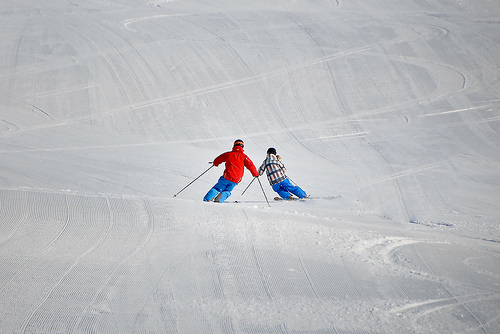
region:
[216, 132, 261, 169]
the head of a man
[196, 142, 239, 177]
the arm of a man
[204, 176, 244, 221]
the legs of a man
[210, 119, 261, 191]
a man wearing a skirt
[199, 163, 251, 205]
the pants on a man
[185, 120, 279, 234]
a man skiing in the snow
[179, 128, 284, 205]
a man holding ski sticks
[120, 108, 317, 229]
people skiing on snow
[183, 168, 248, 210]
a man wearing blue pants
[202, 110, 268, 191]
a man wearing a red coat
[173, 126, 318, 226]
Two skiers in the snow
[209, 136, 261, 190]
skier with red jacket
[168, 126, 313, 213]
Two skiers holding hands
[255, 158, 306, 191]
skier with blue white and red jacket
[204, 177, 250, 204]
skier with blue snow pants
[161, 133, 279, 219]
black ski poles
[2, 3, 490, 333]
ski tracks in the snow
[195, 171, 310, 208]
pair of blue ski pants on the skiers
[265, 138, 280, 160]
Black hats on skier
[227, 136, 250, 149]
Black and red hat on skier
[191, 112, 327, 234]
two people are skiing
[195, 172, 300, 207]
the pants are blue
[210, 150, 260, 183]
the jacket is red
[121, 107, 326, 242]
people holding the ski poles